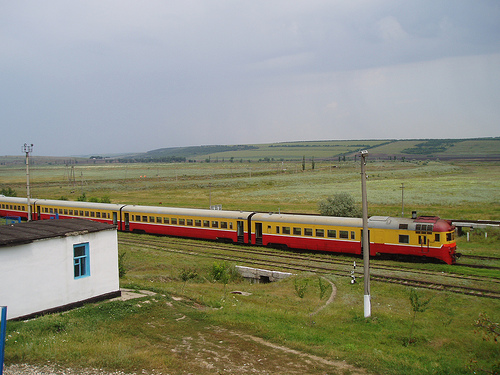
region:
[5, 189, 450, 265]
the train on the tracks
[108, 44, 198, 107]
the sky is gray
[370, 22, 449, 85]
the sky is cloudy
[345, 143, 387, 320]
the pole beside the tracks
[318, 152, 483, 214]
the field of grass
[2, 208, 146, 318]
the building beside the tracks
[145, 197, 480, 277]
the train is yellow and red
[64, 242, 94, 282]
the window of the building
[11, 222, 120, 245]
the roof of the building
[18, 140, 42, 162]
lights above the train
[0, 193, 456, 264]
commuter train is long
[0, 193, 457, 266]
commuter train is red and yellow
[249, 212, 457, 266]
first car of train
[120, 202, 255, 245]
second car of train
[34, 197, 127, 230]
third car of train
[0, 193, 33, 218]
fourth car of train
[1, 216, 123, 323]
white building near train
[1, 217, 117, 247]
brown roof on white building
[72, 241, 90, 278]
window is blue trimmed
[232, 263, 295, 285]
concrete drainage culvert under train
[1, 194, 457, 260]
Long red yellow and gray train.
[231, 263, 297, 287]
Concrete entrance that goes under the tracks.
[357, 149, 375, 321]
Tall wood pole with white base.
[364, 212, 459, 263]
Small first section of a mostly red and yellow train.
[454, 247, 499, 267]
Brown tracks in front of a long train.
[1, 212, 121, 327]
White building with blue window frame and black roof.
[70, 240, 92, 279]
Blue window frame on a white building.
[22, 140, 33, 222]
Power pole towards the back of the train.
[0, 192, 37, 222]
Last section of train that is visible.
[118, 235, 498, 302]
Brown set of empty tracks close to the white building.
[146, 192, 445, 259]
long train on track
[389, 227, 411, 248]
window on side of train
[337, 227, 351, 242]
window on side of train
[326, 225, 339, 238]
window on side of train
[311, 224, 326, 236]
window on side of train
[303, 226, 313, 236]
window on side of train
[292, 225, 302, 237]
window on side of train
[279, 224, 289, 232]
window on side of train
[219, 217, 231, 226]
window on side of train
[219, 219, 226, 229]
window on side of train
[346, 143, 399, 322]
a telephone pole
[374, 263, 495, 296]
a section of railroad tracks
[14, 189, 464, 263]
a yellow and red passenger train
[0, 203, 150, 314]
a small building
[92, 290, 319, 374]
a section of dirt and dead grass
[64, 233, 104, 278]
a window with a blue frame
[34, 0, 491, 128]
a blue and hazy sky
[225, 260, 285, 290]
a stone drain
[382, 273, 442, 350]
a small desert tree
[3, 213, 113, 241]
a black roof on a building